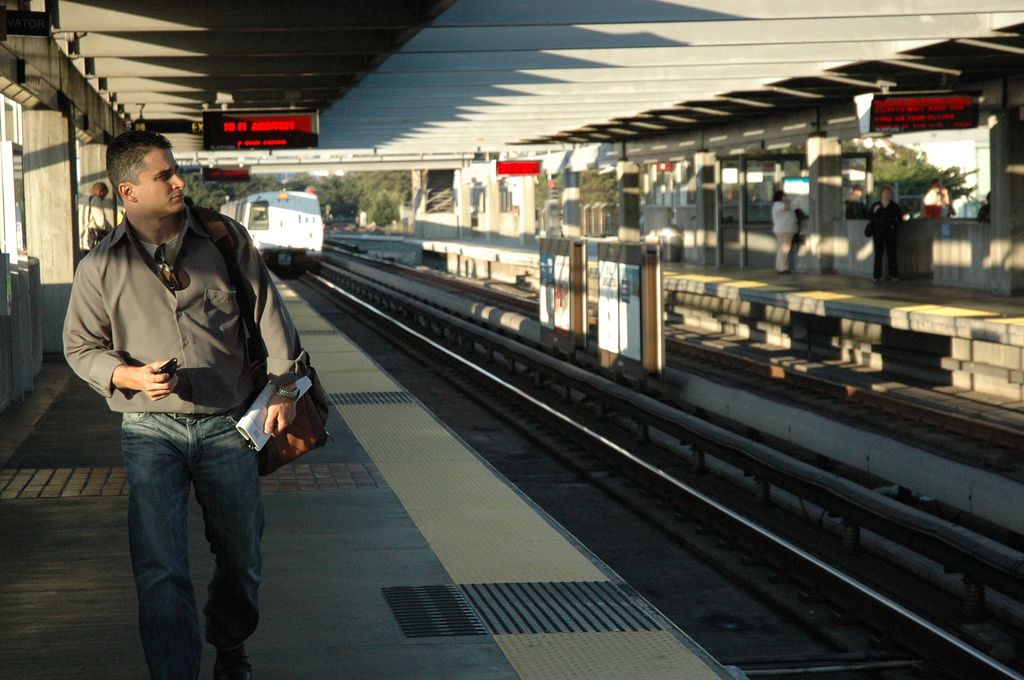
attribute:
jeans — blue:
[110, 400, 262, 662]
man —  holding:
[43, 121, 331, 675]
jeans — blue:
[112, 400, 309, 673]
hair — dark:
[89, 124, 176, 146]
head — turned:
[76, 117, 202, 232]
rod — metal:
[557, 452, 871, 595]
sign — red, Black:
[169, 85, 373, 163]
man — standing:
[56, 122, 335, 606]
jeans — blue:
[114, 402, 344, 645]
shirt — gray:
[47, 202, 387, 445]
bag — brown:
[176, 171, 388, 506]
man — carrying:
[59, 148, 323, 669]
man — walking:
[55, 133, 347, 667]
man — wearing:
[29, 142, 345, 676]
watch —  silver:
[286, 365, 313, 400]